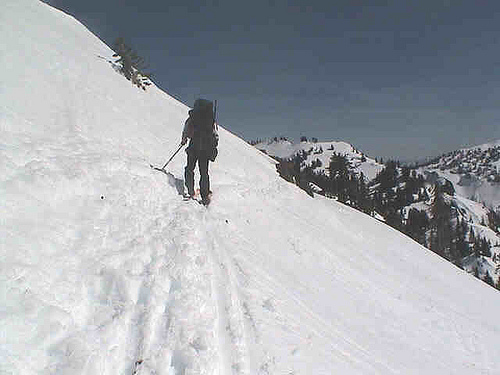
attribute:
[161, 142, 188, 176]
ski pole — one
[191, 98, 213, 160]
backpack — large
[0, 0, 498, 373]
snow — white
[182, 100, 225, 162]
backpack — black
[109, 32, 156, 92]
branch — green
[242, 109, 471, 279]
trees — green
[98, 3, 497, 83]
sky — overcast, grey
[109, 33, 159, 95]
tree — single